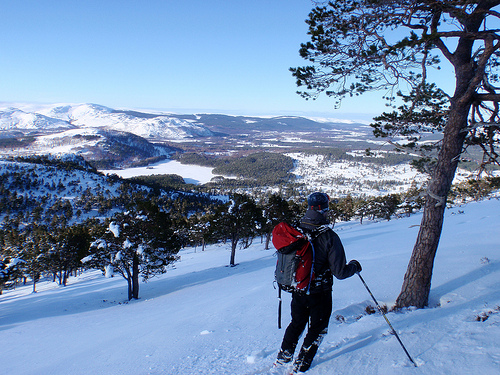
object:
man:
[269, 192, 363, 374]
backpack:
[271, 219, 316, 298]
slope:
[1, 197, 500, 375]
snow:
[3, 310, 231, 375]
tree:
[288, 0, 500, 312]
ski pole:
[356, 272, 420, 367]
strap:
[275, 285, 284, 329]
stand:
[305, 181, 470, 374]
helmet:
[307, 192, 330, 206]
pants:
[279, 288, 333, 364]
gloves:
[349, 259, 363, 272]